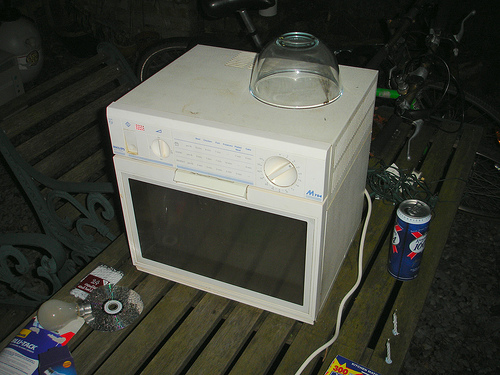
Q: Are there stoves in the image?
A: No, there are no stoves.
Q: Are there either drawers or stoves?
A: No, there are no stoves or drawers.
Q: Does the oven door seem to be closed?
A: Yes, the oven door is closed.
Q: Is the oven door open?
A: No, the oven door is closed.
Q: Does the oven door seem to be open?
A: No, the oven door is closed.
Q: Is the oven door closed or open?
A: The oven door is closed.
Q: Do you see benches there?
A: Yes, there is a bench.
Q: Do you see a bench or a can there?
A: Yes, there is a bench.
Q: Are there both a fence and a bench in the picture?
A: No, there is a bench but no fences.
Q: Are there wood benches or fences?
A: Yes, there is a wood bench.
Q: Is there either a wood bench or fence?
A: Yes, there is a wood bench.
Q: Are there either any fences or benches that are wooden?
A: Yes, the bench is wooden.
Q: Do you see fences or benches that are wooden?
A: Yes, the bench is wooden.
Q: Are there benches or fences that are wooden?
A: Yes, the bench is wooden.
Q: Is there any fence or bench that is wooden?
A: Yes, the bench is wooden.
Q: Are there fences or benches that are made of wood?
A: Yes, the bench is made of wood.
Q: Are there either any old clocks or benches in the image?
A: Yes, there is an old bench.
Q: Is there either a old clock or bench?
A: Yes, there is an old bench.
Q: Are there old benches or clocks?
A: Yes, there is an old bench.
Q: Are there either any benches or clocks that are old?
A: Yes, the bench is old.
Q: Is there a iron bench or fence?
A: Yes, there is an iron bench.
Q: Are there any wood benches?
A: Yes, there is a bench that is made of wood.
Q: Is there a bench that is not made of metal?
A: Yes, there is a bench that is made of wood.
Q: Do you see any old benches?
A: Yes, there is an old bench.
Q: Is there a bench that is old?
A: Yes, there is a bench that is old.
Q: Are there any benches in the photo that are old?
A: Yes, there is a bench that is old.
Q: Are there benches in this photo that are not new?
A: Yes, there is a old bench.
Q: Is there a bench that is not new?
A: Yes, there is a old bench.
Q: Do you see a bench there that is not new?
A: Yes, there is a old bench.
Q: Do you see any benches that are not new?
A: Yes, there is a old bench.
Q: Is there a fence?
A: No, there are no fences.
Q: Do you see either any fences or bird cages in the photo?
A: No, there are no fences or bird cages.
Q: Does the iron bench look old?
A: Yes, the bench is old.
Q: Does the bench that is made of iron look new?
A: No, the bench is old.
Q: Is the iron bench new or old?
A: The bench is old.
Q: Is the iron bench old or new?
A: The bench is old.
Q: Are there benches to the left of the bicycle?
A: Yes, there is a bench to the left of the bicycle.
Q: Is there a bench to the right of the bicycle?
A: No, the bench is to the left of the bicycle.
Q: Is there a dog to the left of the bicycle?
A: No, there is a bench to the left of the bicycle.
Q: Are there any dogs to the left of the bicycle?
A: No, there is a bench to the left of the bicycle.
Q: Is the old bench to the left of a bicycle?
A: Yes, the bench is to the left of a bicycle.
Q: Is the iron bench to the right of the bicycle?
A: No, the bench is to the left of the bicycle.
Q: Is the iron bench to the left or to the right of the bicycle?
A: The bench is to the left of the bicycle.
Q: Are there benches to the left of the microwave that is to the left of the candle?
A: Yes, there is a bench to the left of the microwave.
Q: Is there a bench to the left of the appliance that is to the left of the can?
A: Yes, there is a bench to the left of the microwave.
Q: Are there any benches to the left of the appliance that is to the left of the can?
A: Yes, there is a bench to the left of the microwave.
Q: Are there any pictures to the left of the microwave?
A: No, there is a bench to the left of the microwave.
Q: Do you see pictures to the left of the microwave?
A: No, there is a bench to the left of the microwave.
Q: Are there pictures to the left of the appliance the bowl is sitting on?
A: No, there is a bench to the left of the microwave.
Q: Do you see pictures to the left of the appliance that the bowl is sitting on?
A: No, there is a bench to the left of the microwave.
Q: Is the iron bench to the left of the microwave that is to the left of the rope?
A: Yes, the bench is to the left of the microwave.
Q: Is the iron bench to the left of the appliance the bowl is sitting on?
A: Yes, the bench is to the left of the microwave.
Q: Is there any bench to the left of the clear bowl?
A: Yes, there is a bench to the left of the bowl.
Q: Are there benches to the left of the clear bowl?
A: Yes, there is a bench to the left of the bowl.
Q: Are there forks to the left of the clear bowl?
A: No, there is a bench to the left of the bowl.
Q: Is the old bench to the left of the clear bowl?
A: Yes, the bench is to the left of the bowl.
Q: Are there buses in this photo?
A: No, there are no buses.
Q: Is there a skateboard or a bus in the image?
A: No, there are no buses or skateboards.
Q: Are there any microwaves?
A: Yes, there is a microwave.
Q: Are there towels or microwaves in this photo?
A: Yes, there is a microwave.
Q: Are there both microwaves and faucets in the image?
A: No, there is a microwave but no faucets.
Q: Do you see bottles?
A: No, there are no bottles.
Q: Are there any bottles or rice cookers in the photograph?
A: No, there are no bottles or rice cookers.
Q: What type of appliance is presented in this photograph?
A: The appliance is a microwave.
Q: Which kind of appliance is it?
A: The appliance is a microwave.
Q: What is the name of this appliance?
A: This is a microwave.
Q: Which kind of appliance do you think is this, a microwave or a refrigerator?
A: This is a microwave.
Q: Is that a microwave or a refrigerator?
A: That is a microwave.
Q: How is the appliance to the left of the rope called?
A: The appliance is a microwave.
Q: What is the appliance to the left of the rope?
A: The appliance is a microwave.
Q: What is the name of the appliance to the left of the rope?
A: The appliance is a microwave.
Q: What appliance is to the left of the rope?
A: The appliance is a microwave.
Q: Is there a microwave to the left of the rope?
A: Yes, there is a microwave to the left of the rope.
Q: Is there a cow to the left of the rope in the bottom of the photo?
A: No, there is a microwave to the left of the rope.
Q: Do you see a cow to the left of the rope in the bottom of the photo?
A: No, there is a microwave to the left of the rope.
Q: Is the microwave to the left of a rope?
A: Yes, the microwave is to the left of a rope.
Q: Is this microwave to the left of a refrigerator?
A: No, the microwave is to the left of a rope.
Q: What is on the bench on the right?
A: The microwave is on the bench.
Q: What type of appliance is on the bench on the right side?
A: The appliance is a microwave.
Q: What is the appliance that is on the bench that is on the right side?
A: The appliance is a microwave.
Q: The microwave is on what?
A: The microwave is on the bench.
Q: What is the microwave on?
A: The microwave is on the bench.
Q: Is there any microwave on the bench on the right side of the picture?
A: Yes, there is a microwave on the bench.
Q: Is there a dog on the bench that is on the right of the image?
A: No, there is a microwave on the bench.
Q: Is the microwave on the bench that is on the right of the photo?
A: Yes, the microwave is on the bench.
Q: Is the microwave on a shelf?
A: No, the microwave is on the bench.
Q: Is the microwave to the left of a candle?
A: Yes, the microwave is to the left of a candle.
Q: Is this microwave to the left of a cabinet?
A: No, the microwave is to the left of a candle.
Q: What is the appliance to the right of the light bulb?
A: The appliance is a microwave.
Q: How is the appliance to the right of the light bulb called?
A: The appliance is a microwave.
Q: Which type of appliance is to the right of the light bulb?
A: The appliance is a microwave.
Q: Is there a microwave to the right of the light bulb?
A: Yes, there is a microwave to the right of the light bulb.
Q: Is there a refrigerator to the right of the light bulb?
A: No, there is a microwave to the right of the light bulb.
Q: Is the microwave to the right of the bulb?
A: Yes, the microwave is to the right of the bulb.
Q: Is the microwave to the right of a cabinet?
A: No, the microwave is to the right of the bulb.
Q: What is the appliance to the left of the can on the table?
A: The appliance is a microwave.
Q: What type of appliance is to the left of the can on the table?
A: The appliance is a microwave.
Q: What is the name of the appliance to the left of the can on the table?
A: The appliance is a microwave.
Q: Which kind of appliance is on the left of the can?
A: The appliance is a microwave.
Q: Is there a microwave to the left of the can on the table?
A: Yes, there is a microwave to the left of the can.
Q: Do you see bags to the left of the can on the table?
A: No, there is a microwave to the left of the can.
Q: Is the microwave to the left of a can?
A: Yes, the microwave is to the left of a can.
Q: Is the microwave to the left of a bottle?
A: No, the microwave is to the left of a can.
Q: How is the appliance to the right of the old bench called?
A: The appliance is a microwave.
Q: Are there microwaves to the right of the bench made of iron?
A: Yes, there is a microwave to the right of the bench.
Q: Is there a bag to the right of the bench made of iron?
A: No, there is a microwave to the right of the bench.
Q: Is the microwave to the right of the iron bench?
A: Yes, the microwave is to the right of the bench.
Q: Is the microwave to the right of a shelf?
A: No, the microwave is to the right of the bench.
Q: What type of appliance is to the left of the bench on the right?
A: The appliance is a microwave.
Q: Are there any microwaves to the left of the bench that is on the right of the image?
A: Yes, there is a microwave to the left of the bench.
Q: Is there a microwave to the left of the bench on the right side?
A: Yes, there is a microwave to the left of the bench.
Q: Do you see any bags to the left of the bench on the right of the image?
A: No, there is a microwave to the left of the bench.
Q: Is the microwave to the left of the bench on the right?
A: Yes, the microwave is to the left of the bench.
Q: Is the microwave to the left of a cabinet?
A: No, the microwave is to the left of the bench.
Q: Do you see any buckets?
A: No, there are no buckets.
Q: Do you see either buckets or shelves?
A: No, there are no buckets or shelves.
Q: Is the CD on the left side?
A: Yes, the CD is on the left of the image.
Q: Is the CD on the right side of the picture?
A: No, the CD is on the left of the image.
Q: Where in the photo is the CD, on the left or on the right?
A: The CD is on the left of the image.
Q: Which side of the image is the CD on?
A: The CD is on the left of the image.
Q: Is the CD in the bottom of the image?
A: Yes, the CD is in the bottom of the image.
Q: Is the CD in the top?
A: No, the CD is in the bottom of the image.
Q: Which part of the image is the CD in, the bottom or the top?
A: The CD is in the bottom of the image.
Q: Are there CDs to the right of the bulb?
A: Yes, there is a CD to the right of the bulb.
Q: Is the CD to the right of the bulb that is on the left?
A: Yes, the CD is to the right of the bulb.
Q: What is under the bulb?
A: The CD is under the bulb.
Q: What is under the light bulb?
A: The CD is under the bulb.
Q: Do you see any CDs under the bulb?
A: Yes, there is a CD under the bulb.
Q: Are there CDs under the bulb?
A: Yes, there is a CD under the bulb.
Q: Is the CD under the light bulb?
A: Yes, the CD is under the light bulb.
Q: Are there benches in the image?
A: Yes, there is a bench.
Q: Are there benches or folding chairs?
A: Yes, there is a bench.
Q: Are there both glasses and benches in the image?
A: No, there is a bench but no glasses.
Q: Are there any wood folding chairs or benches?
A: Yes, there is a wood bench.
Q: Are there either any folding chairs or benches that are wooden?
A: Yes, the bench is wooden.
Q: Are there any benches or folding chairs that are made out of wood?
A: Yes, the bench is made of wood.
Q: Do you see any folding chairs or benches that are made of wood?
A: Yes, the bench is made of wood.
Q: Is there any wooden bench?
A: Yes, there is a wood bench.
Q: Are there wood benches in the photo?
A: Yes, there is a wood bench.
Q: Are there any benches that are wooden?
A: Yes, there is a bench that is wooden.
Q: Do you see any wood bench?
A: Yes, there is a bench that is made of wood.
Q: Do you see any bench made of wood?
A: Yes, there is a bench that is made of wood.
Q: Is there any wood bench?
A: Yes, there is a bench that is made of wood.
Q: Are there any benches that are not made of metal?
A: Yes, there is a bench that is made of wood.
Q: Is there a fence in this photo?
A: No, there are no fences.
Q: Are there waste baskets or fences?
A: No, there are no fences or waste baskets.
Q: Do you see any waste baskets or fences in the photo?
A: No, there are no fences or waste baskets.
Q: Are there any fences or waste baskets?
A: No, there are no fences or waste baskets.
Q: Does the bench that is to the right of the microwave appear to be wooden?
A: Yes, the bench is wooden.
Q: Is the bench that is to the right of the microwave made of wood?
A: Yes, the bench is made of wood.